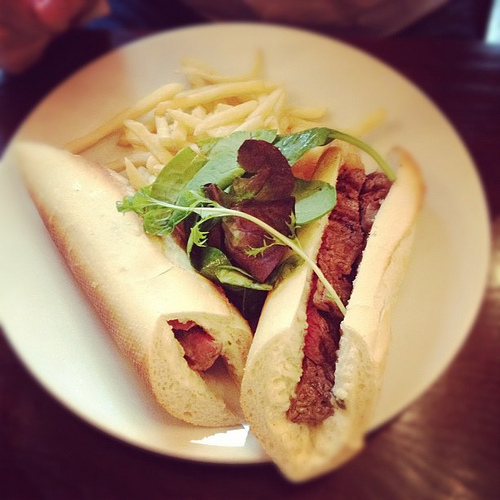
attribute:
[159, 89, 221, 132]
fries — yellow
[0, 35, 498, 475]
plate — round, white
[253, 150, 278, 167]
lettuce — purple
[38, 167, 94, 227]
bread — roll, round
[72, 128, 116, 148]
frie — golden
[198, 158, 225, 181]
lettuce — green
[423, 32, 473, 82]
table — dark